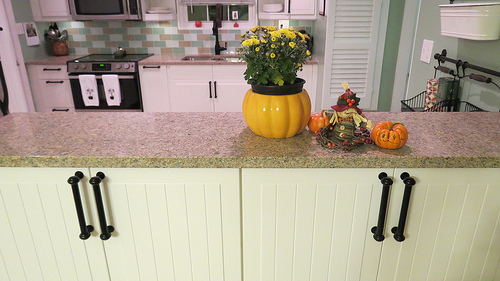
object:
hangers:
[400, 49, 500, 88]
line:
[221, 165, 261, 281]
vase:
[237, 88, 316, 139]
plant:
[234, 22, 312, 86]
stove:
[62, 46, 151, 112]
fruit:
[192, 19, 206, 28]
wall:
[42, 22, 254, 57]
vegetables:
[310, 79, 406, 154]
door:
[316, 0, 390, 111]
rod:
[433, 50, 500, 79]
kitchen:
[0, 0, 500, 281]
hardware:
[206, 80, 220, 100]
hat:
[330, 80, 364, 115]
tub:
[183, 53, 252, 65]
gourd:
[369, 120, 411, 152]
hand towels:
[76, 73, 123, 107]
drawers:
[25, 62, 79, 114]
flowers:
[234, 22, 315, 89]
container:
[45, 35, 72, 58]